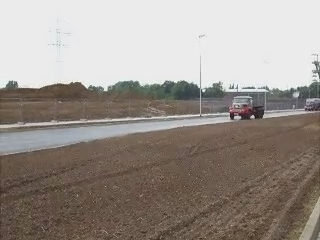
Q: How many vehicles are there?
A: Two.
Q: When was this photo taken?
A: During the daytime.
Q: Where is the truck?
A: On a road.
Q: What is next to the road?
A: A dirt field.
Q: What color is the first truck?
A: Red.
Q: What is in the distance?
A: An electrical tower.